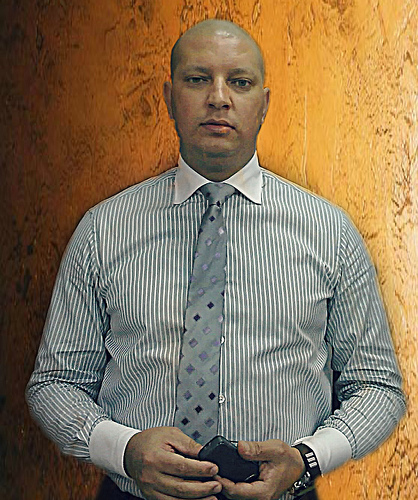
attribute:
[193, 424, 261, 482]
cell phone — black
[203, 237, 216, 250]
diamond — purple, small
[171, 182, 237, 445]
tie — gray, purple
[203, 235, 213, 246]
purple diamond — small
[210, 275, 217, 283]
diamonds — small, purple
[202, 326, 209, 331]
diamonds — small, purple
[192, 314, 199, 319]
diamonds — small, purple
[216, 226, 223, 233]
diamonds — small, purple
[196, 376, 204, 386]
diamonds — small, purple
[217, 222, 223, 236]
purple diamond — small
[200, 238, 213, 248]
purple diamond — small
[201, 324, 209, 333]
purple diamond — small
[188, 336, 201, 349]
purple diamond — small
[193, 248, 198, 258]
diamond — small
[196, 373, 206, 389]
diamond — small, purple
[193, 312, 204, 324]
diamond — purple, small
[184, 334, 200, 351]
diamond — purple, small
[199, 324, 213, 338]
diamond — purple, small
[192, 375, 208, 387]
diamond — purple, small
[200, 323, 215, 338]
diamond — small, purple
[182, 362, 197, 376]
diamond — small, purple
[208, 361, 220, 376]
diamond — purple, small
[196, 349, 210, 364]
diamond — purple, small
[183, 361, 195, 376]
diamond — purple, small